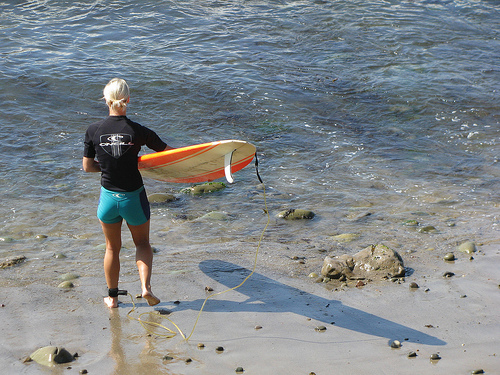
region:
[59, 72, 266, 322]
The woman holds a surfboard.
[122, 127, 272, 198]
The surfboard is orange and white.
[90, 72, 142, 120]
The woman is blonde.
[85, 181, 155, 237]
The woman wears blue shorts.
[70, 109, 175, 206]
The woman's top is black.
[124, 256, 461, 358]
The surfboard's shadow is on the sand.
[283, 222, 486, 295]
Rocks are on the sand.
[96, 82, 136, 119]
The woman's hair is tied back.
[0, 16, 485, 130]
Ripples are in the water.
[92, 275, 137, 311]
An object is attached to the woman's ankle.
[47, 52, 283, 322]
Woman getting ready to surf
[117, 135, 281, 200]
Surfboard is orange and white.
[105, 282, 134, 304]
Surfboard leash attached to her ankle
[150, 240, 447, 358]
The woman's shadow to her right.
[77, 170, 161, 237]
The woman is wearing blue shorts.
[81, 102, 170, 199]
The woman's top is black.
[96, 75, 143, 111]
The woman is blond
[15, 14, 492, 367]
Photo taken at the beach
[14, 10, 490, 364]
Photo taken during the summer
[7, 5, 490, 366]
The weather is sunny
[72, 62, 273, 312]
girl standing in the water.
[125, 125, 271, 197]
girl holding a surfboard.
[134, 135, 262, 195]
surfboard is white and orange.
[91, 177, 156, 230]
girl's shorts are blue.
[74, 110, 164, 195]
girl's shirt is black.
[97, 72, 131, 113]
girl's hair is blonde.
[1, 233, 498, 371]
the sand is brown.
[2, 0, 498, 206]
the water is blue.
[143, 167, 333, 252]
rocks in the water.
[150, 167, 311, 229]
the rocks are grey.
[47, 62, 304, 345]
woman with a surfboard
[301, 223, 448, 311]
large brown rock on sand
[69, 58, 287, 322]
woman with orange and white surfboard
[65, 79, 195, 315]
woman with blue shorts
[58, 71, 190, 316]
woman with black top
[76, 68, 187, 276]
woman has blond hair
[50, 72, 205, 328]
black and white shirt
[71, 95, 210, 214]
white lettering on black shirt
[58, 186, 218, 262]
blue shorts with black stripe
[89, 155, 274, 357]
yellow and black cord from surfboard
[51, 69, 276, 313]
a woman holding a surfboard.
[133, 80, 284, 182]
an orange and white surfboard.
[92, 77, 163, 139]
a girl with blonde hair.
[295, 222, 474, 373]
a rock in the ocean.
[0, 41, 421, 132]
a wave in the ocean.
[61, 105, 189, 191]
a black t shirt.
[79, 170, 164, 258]
a pair of tight blue shorts.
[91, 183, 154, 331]
the bottom half of a woman.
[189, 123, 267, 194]
the back end of a surfboard.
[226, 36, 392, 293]
a large pool of water.